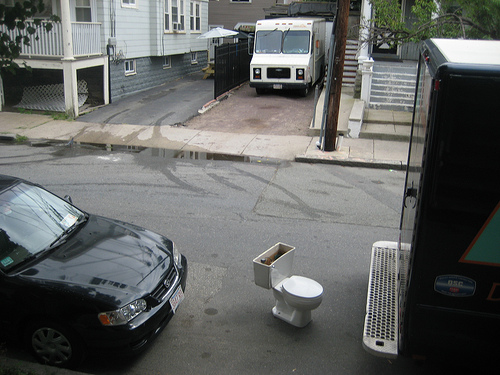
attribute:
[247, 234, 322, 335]
toilet — white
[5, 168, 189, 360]
car — parked, black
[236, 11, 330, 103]
truck — white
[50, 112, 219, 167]
sidewalk — wet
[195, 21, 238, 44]
umbrella — white